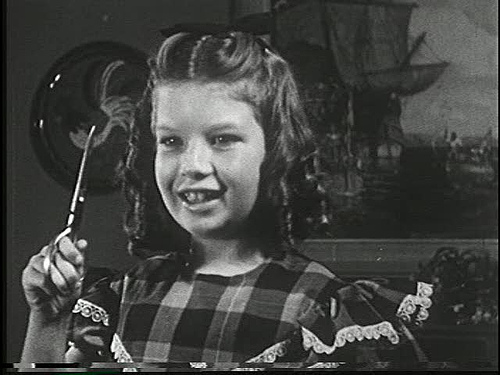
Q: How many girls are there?
A: 1.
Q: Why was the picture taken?
A: To show the girl.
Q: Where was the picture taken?
A: In a living room.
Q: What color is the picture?
A: Black and white.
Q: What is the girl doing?
A: Smiling.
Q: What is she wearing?
A: A dress.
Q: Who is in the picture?
A: A girl.